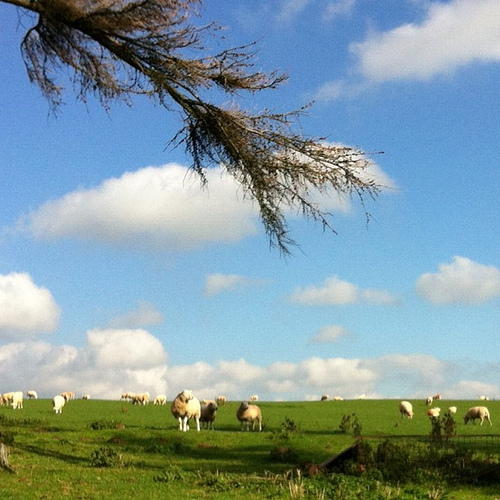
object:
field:
[0, 397, 499, 499]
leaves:
[2, 0, 404, 264]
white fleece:
[432, 408, 439, 416]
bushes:
[322, 437, 413, 480]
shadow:
[0, 422, 499, 486]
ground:
[2, 399, 500, 500]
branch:
[0, 0, 394, 259]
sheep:
[2, 387, 28, 413]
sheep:
[233, 401, 265, 434]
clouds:
[7, 145, 394, 254]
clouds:
[298, 0, 500, 115]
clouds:
[0, 269, 60, 339]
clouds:
[416, 255, 500, 305]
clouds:
[289, 272, 397, 308]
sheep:
[235, 400, 261, 430]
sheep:
[398, 397, 413, 419]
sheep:
[464, 405, 493, 427]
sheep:
[169, 387, 204, 433]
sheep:
[49, 395, 69, 415]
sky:
[0, 0, 499, 399]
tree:
[0, 0, 396, 256]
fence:
[354, 432, 499, 456]